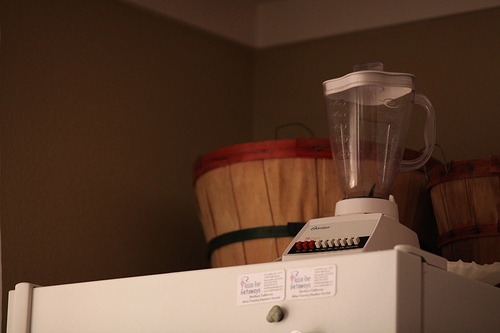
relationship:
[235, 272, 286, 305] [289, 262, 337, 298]
there is a note. notes are written there is a note.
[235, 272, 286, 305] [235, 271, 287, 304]
there is a note. re are notes there is a note.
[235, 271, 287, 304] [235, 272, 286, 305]
there is a note. notes are written there is a note.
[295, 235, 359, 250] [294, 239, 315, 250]
there are buttons. buttons are white buttons are red.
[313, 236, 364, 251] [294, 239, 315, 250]
buttons are white. re are buttons buttons are red.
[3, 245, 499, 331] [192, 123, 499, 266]
there is refrigerato baskets are two there are baskets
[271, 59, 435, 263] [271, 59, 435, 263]
blender is empty re a blender blender is empty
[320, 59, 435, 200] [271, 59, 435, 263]
blender is empty re a blender blender is empty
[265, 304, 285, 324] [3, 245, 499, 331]
there is a magnet. re refrigerato magnet on refrigerat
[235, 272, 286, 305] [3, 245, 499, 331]
there is a card re a card cards on refrigerato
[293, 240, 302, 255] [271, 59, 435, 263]
buttons  on blender three red buttons blender is empty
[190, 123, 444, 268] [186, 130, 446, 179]
there is a basket. basket has an edge edge is red.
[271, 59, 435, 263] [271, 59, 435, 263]
blender is empty re a fridge blender is empty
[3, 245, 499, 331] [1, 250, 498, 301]
fridge is white. re a fridge fridge has top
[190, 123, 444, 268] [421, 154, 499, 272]
there is a basket. basket fragile there are baskets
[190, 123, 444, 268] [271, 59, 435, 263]
there is a basket. re a basket blender is empty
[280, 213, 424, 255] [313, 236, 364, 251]
blender has buttons buttons are red buttons are white.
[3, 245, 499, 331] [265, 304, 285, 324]
there is a fridge magnet on fridge there is a magnet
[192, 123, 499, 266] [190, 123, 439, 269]
there are baskets re a blender there is a basket.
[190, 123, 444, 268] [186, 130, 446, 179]
there is a basket. basket has red top basket top is red.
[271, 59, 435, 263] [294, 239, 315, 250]
blender is empty blender has buttons buttons are red.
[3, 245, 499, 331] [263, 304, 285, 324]
there is a fridge. magnets are two there is a magnet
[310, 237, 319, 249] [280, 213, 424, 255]
there are buttons. re a botton buttons  on blender